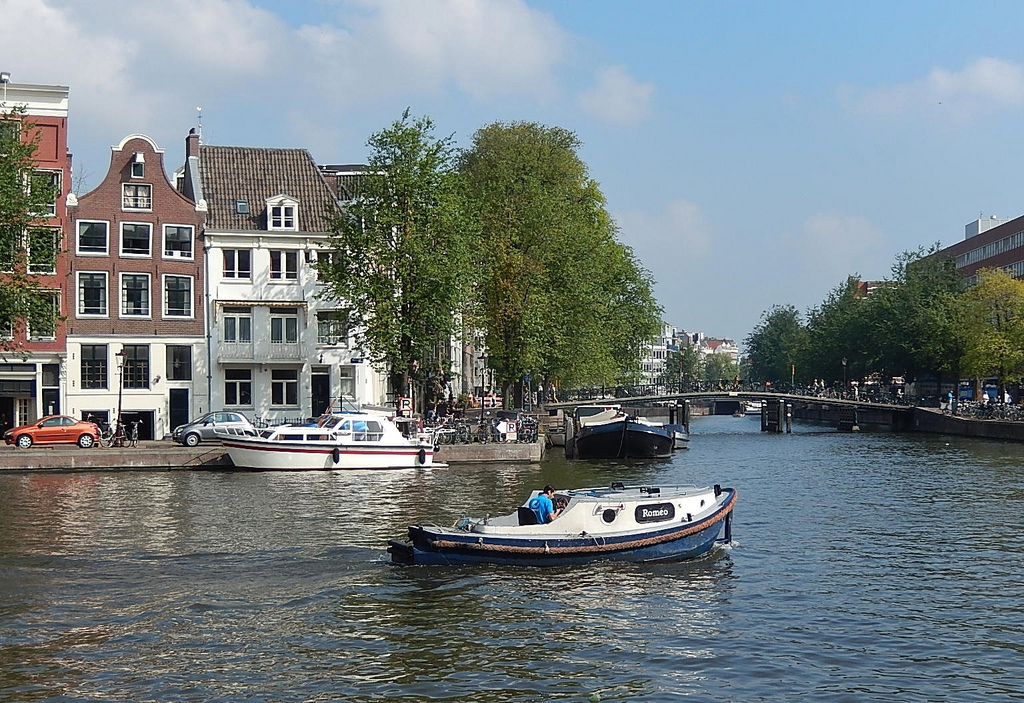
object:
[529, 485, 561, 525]
man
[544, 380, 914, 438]
bridge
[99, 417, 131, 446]
bicycle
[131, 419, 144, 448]
bicycle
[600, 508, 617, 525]
window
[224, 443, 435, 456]
stripe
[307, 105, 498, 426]
tree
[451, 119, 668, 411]
trees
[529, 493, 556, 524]
shirt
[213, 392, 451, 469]
boat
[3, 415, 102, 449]
car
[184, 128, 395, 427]
building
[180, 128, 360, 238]
roof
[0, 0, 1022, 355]
sky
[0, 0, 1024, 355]
clouds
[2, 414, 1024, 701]
water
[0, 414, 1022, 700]
ripples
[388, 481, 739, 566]
boat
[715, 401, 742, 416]
water way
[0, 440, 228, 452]
street